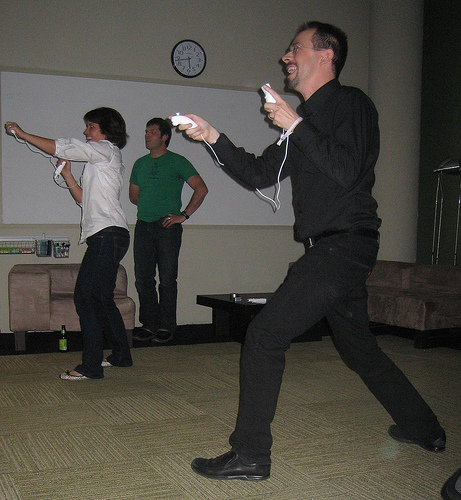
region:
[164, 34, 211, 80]
Clock on wall reading 5:44.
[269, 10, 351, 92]
Smiling caucasian man.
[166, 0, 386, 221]
Smiling caucasian man playing Wii game.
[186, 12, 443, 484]
Smiling man dressed in black.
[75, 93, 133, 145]
Smiling woman with short, dark hair.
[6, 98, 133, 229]
Dark haired female in white shirt.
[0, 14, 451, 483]
Male and female engaged in Wii game.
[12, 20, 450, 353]
Male in green shirt watching Wii game.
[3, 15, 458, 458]
Three people wearing black pants.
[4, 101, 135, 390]
Dark haired female wearing white shirt, black pants and flipflops.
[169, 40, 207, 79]
A clock on a wall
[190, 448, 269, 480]
A black shoe on a foot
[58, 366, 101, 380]
A casual dress shoe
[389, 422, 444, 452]
Dark colored shoe on foot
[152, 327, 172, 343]
A shoe on a guy's foot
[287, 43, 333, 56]
Glasses worn by a guy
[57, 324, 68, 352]
Green bottle on floor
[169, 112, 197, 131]
A video game controller in hand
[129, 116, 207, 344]
Guy watching people play games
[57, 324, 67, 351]
Bottle that is green labeled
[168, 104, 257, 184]
The man is holding a wii controller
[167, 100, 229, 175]
The wii controller is white.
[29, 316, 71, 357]
There is a green bottle sitting on the floor.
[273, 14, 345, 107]
The man is laughing.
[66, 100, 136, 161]
The woman is laughing.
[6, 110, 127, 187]
The woman is holding a wii controller.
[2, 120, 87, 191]
The wii controller is white.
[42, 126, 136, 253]
The woman is wearing a white blouse.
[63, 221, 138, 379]
The woman is wearing black pants.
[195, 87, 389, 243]
The man is wearing a black shirt.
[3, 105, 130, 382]
woman in white and jeans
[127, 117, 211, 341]
man in green shirt and jeans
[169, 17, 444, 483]
man in all black attire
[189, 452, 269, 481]
shiny black leather loafer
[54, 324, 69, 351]
bottle of sierra nevada beer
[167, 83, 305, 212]
white wii remote with attached nunchuck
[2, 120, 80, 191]
white wii remote with attached nunchuck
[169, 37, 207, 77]
white clock face with black numbers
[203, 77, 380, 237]
long sleeved collared black shirt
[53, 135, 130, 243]
long sleeved collared white shirt